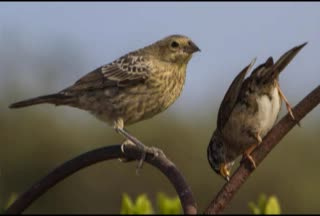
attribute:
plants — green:
[117, 178, 201, 215]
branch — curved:
[1, 143, 197, 214]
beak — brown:
[185, 40, 200, 53]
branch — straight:
[243, 129, 300, 162]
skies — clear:
[2, 4, 108, 50]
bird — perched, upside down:
[217, 71, 278, 168]